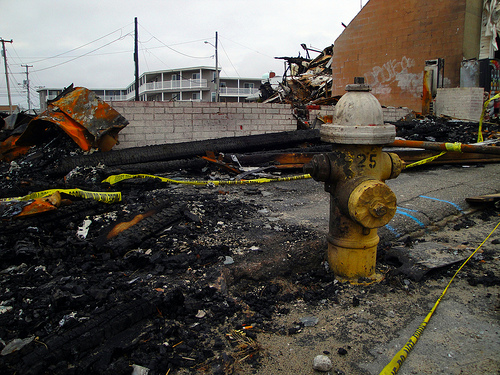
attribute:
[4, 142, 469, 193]
tape — yellow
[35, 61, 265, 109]
building — brown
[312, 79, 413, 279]
hydrant — yellow, 25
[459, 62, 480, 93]
smoke — grey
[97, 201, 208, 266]
area — burnt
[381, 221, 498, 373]
police tape — yellow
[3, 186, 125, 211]
police tape — yellow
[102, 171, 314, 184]
police tape — yellow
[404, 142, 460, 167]
police tape — yellow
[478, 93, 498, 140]
police tape — yellow